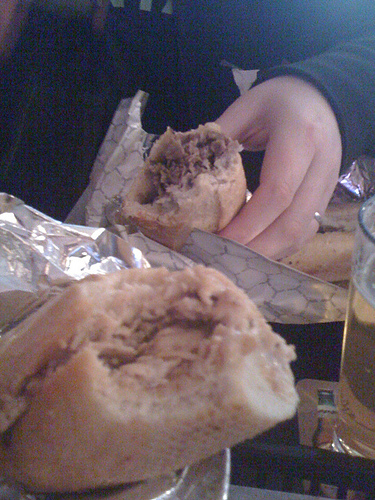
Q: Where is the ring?
A: The hand.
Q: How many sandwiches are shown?
A: Two.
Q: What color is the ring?
A: Silver.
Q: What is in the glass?
A: Beer.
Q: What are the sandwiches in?
A: Paper.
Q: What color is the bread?
A: Tan.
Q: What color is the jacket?
A: Black.